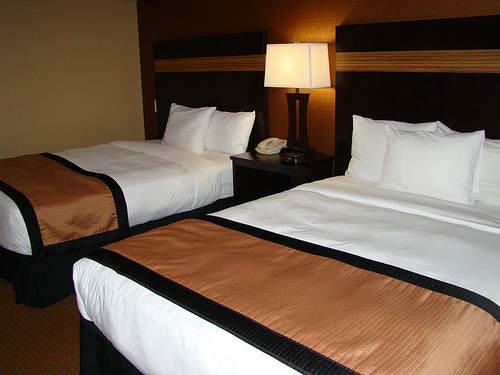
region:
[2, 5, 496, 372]
A hotel bedroom with double beds.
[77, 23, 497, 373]
A bed with a dark colored headboard.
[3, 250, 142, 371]
Black bedskirts.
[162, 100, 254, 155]
White pillows on the bed.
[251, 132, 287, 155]
A white corded telephone.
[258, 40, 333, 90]
A white lamp shade.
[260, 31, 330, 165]
A lamp turned on.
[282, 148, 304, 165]
An alarm clock.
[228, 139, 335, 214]
A dark colored nightstand.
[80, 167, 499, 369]
White sheets on a bed with a gold and black runner across the foot of the bed.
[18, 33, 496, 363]
twin beds next to each other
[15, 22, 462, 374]
two hotel beds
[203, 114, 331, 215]
a night stand in between beds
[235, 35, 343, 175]
a lamp on table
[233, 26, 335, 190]
a phone on the table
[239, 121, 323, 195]
a clock on a table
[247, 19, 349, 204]
a lamp on a night stand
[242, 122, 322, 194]
a telephone on a night stand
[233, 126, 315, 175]
a clock on a night stand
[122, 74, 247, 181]
pillows on a bed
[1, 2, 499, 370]
room at a hotel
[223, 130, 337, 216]
black bedstand between two beds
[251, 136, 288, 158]
phone sitting on a bedstand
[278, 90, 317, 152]
base of a lamp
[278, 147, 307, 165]
clock on a bedside table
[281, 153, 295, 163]
digital display on a clock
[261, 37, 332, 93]
illuminated lampshade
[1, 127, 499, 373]
two beds in a hotel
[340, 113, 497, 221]
three pillows on the right bed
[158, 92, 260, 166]
white pillows on the left bed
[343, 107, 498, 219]
Three pillows are on the bed.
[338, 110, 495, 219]
The pillows are white.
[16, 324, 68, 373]
The floor is brown.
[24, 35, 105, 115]
The wall is yellow.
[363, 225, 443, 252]
The bed is white.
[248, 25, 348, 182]
A lamp.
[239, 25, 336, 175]
The lamp is on.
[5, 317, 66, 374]
The floor has carpet on it.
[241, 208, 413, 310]
The bed is brown, black and white.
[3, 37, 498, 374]
Two beds are in the picture.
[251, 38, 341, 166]
Table lamp in the on position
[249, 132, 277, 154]
Land line phone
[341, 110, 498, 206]
Three white pillows in a pyramid fashion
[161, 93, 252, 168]
Two white pillows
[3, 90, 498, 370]
Two queen size beds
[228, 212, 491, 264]
Clean white sheets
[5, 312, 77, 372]
Brown floor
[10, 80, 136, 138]
tan or beige walls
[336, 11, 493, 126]
Black and brown headboard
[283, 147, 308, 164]
black and red Alarm clock